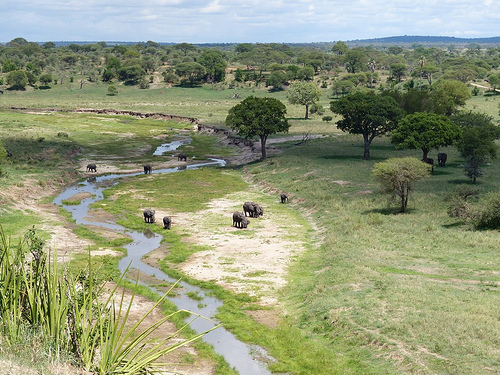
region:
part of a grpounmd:
[243, 250, 300, 310]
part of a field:
[343, 261, 390, 361]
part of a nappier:
[96, 299, 132, 337]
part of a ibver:
[232, 333, 254, 360]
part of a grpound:
[353, 294, 385, 344]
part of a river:
[211, 289, 243, 321]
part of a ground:
[333, 255, 374, 317]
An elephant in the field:
[160, 213, 178, 233]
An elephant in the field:
[140, 205, 157, 225]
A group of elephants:
[230, 209, 249, 229]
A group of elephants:
[242, 196, 264, 216]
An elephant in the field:
[277, 187, 299, 208]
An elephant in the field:
[139, 157, 158, 177]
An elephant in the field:
[170, 152, 194, 167]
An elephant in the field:
[85, 159, 101, 172]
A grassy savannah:
[220, 236, 498, 363]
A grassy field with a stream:
[7, 44, 499, 365]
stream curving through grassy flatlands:
[2, 95, 293, 372]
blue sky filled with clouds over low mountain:
[0, 0, 491, 42]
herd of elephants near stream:
[80, 150, 295, 250]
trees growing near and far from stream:
[5, 40, 490, 225]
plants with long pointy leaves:
[0, 220, 225, 365]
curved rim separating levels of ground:
[10, 100, 252, 155]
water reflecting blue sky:
[46, 130, 286, 370]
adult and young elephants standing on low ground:
[137, 185, 289, 230]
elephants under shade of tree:
[417, 135, 450, 172]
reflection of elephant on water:
[81, 157, 103, 187]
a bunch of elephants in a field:
[73, 142, 302, 294]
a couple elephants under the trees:
[411, 148, 462, 190]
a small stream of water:
[37, 115, 284, 373]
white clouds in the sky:
[25, 3, 478, 53]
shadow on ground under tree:
[221, 147, 278, 180]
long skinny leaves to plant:
[13, 232, 222, 374]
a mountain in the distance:
[331, 25, 498, 67]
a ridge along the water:
[103, 108, 255, 170]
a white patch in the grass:
[173, 190, 286, 317]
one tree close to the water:
[207, 85, 311, 172]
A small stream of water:
[49, 128, 289, 373]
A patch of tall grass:
[1, 225, 224, 373]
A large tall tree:
[226, 96, 291, 158]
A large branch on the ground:
[293, 129, 313, 148]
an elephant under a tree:
[434, 151, 449, 166]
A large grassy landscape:
[1, 68, 498, 371]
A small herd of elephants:
[82, 151, 291, 230]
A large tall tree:
[330, 89, 405, 159]